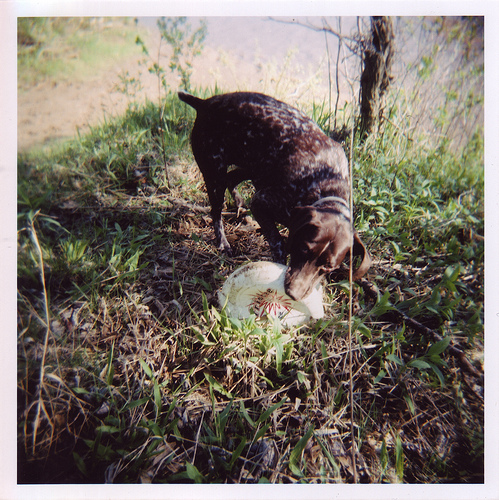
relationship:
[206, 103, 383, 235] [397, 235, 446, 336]
dog in grass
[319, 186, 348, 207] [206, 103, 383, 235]
collar on dog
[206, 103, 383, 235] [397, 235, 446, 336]
dog on grass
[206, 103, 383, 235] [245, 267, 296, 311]
dog with frisbee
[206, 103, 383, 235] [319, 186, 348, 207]
dog with collar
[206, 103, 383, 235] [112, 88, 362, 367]
dog in outside